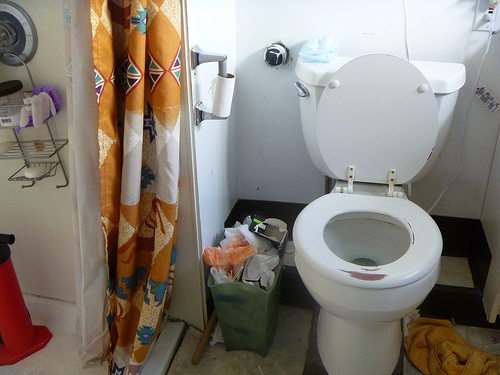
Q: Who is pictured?
A: No one is pictured.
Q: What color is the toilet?
A: White.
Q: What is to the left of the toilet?
A: A trash can.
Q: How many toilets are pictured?
A: One.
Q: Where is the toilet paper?
A: To the left of the trash can.